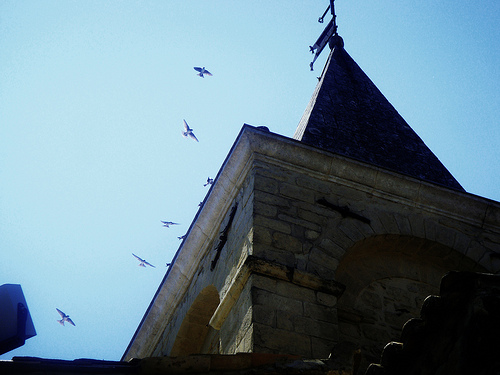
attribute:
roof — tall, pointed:
[277, 26, 482, 227]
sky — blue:
[43, 67, 131, 189]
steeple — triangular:
[290, 45, 470, 192]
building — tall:
[191, 60, 388, 291]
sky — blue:
[2, 0, 158, 243]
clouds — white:
[392, 15, 459, 94]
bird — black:
[194, 64, 211, 79]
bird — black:
[200, 177, 215, 187]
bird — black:
[162, 221, 175, 228]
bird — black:
[132, 251, 152, 268]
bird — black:
[56, 308, 76, 328]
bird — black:
[181, 119, 200, 144]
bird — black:
[158, 219, 179, 229]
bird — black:
[126, 251, 156, 270]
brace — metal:
[268, 178, 378, 235]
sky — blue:
[0, 0, 499, 362]